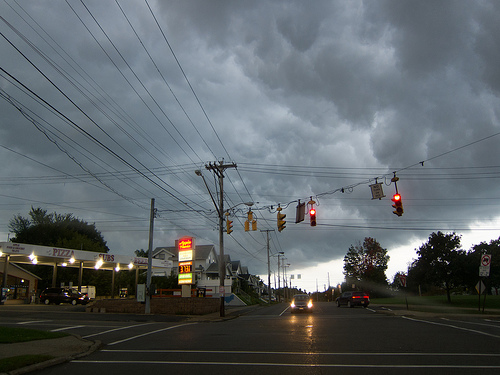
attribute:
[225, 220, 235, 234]
light case — yellow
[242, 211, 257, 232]
light case — yellow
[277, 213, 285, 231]
light case — yellow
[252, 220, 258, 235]
light case — yellow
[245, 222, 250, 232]
light case — yellow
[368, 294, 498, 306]
grass — green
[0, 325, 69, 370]
grass — green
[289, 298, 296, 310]
light — on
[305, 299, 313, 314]
light — on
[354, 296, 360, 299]
light — red, on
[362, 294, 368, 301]
light — red, on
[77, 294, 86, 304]
light — on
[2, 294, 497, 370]
street — black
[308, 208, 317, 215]
light — red, hanging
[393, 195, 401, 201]
light — red, hanging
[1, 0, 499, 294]
sky — cloudy, gray, overcast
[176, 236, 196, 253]
sig — advertisig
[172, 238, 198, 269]
sign — red, yellow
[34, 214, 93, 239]
tree — green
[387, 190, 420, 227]
signal — hanging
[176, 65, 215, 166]
wires — overhead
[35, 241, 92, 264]
sign — red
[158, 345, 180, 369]
lines — white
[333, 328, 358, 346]
road — wet